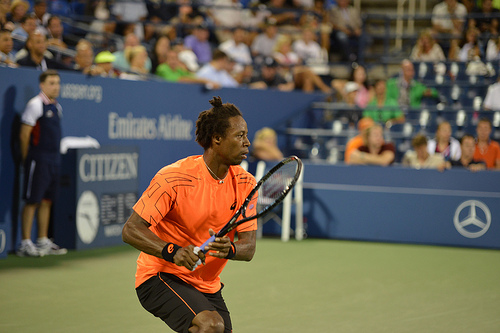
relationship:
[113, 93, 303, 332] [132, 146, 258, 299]
tennis player has shirt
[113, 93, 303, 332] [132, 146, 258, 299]
tennis player wearing shirt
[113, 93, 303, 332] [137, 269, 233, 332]
tennis player wearing shorts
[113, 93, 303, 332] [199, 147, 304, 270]
tennis player holding racket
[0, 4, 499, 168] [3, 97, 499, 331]
audience watching tennis match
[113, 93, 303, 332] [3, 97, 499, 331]
tennis player in tennis match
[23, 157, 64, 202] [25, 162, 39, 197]
shorts with stripe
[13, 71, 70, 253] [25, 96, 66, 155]
man wearing shirt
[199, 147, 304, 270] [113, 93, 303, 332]
racket held by tennis player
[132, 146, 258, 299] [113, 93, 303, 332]
shirt on tennis player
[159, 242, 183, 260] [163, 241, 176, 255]
wristband with design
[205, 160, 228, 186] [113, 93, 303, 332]
necklace on tennis player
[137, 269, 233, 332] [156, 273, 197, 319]
shorts with stripe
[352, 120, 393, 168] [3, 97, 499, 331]
spectator at tennis match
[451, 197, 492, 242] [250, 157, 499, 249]
sponsor on wall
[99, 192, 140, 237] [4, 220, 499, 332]
clock at court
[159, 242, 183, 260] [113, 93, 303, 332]
wristband on tennis player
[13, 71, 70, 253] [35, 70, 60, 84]
man has hair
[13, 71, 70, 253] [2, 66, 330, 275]
man standing against wall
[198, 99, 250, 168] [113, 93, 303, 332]
head of tennis player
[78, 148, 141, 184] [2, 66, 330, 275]
sponsor on wall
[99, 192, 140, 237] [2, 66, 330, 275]
clock on wall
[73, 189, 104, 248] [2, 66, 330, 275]
clock on wall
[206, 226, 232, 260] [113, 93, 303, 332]
left hand of tennis player